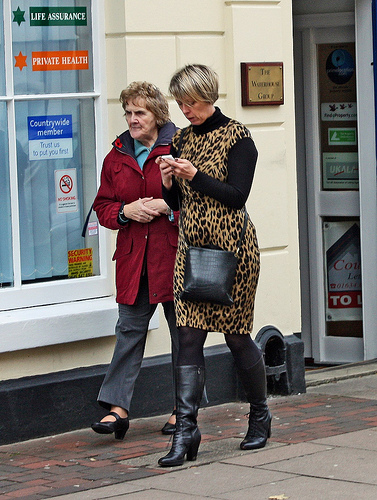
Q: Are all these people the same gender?
A: Yes, all the people are female.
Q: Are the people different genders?
A: No, all the people are female.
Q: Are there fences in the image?
A: No, there are no fences.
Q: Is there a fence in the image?
A: No, there are no fences.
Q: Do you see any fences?
A: No, there are no fences.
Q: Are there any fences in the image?
A: No, there are no fences.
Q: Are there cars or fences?
A: No, there are no fences or cars.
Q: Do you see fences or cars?
A: No, there are no fences or cars.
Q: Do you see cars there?
A: No, there are no cars.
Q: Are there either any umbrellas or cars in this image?
A: No, there are no cars or umbrellas.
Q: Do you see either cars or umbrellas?
A: No, there are no cars or umbrellas.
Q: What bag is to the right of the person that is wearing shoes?
A: The bag is a handbag.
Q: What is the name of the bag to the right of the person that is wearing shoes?
A: The bag is a handbag.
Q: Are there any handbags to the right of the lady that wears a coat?
A: Yes, there is a handbag to the right of the lady.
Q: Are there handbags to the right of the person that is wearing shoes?
A: Yes, there is a handbag to the right of the lady.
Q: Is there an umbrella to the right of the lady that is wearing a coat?
A: No, there is a handbag to the right of the lady.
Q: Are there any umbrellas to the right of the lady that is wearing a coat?
A: No, there is a handbag to the right of the lady.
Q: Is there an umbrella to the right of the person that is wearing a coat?
A: No, there is a handbag to the right of the lady.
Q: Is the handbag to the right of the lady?
A: Yes, the handbag is to the right of the lady.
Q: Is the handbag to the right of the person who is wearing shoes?
A: Yes, the handbag is to the right of the lady.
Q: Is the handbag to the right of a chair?
A: No, the handbag is to the right of the lady.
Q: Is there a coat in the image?
A: Yes, there is a coat.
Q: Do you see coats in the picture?
A: Yes, there is a coat.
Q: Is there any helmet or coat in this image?
A: Yes, there is a coat.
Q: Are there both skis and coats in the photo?
A: No, there is a coat but no skis.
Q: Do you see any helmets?
A: No, there are no helmets.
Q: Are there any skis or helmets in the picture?
A: No, there are no helmets or skis.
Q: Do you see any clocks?
A: No, there are no clocks.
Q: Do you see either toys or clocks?
A: No, there are no clocks or toys.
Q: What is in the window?
A: The sticker is in the window.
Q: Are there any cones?
A: No, there are no cones.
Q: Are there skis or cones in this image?
A: No, there are no cones or skis.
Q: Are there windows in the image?
A: Yes, there is a window.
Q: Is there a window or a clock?
A: Yes, there is a window.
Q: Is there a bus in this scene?
A: No, there are no buses.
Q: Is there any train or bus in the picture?
A: No, there are no buses or trains.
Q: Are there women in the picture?
A: Yes, there are women.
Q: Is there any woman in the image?
A: Yes, there are women.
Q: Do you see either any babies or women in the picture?
A: Yes, there are women.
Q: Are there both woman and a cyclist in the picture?
A: No, there are women but no cyclists.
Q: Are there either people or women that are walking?
A: Yes, the women are walking.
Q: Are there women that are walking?
A: Yes, there are women that are walking.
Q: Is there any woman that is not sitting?
A: Yes, there are women that are walking.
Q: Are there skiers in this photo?
A: No, there are no skiers.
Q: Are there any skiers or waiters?
A: No, there are no skiers or waiters.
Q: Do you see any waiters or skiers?
A: No, there are no skiers or waiters.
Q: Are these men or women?
A: These are women.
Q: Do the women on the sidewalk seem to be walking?
A: Yes, the women are walking.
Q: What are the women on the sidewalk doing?
A: The women are walking.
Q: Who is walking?
A: The women are walking.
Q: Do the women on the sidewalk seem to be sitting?
A: No, the women are walking.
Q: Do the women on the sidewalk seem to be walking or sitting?
A: The women are walking.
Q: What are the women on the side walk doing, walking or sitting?
A: The women are walking.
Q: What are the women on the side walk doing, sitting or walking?
A: The women are walking.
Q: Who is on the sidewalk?
A: The women are on the sidewalk.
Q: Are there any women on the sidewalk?
A: Yes, there are women on the sidewalk.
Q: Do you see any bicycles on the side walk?
A: No, there are women on the side walk.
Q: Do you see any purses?
A: Yes, there is a purse.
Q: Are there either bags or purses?
A: Yes, there is a purse.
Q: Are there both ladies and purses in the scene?
A: Yes, there are both a purse and a lady.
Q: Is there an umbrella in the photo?
A: No, there are no umbrellas.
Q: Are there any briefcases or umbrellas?
A: No, there are no umbrellas or briefcases.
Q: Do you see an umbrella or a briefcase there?
A: No, there are no umbrellas or briefcases.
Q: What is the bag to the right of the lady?
A: The bag is a purse.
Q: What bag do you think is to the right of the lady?
A: The bag is a purse.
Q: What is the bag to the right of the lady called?
A: The bag is a purse.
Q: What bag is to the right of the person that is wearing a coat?
A: The bag is a purse.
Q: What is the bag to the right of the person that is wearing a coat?
A: The bag is a purse.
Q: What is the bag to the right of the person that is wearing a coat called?
A: The bag is a purse.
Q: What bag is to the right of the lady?
A: The bag is a purse.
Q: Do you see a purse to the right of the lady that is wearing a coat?
A: Yes, there is a purse to the right of the lady.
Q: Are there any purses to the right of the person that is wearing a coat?
A: Yes, there is a purse to the right of the lady.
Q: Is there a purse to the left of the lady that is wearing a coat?
A: No, the purse is to the right of the lady.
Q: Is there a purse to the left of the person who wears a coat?
A: No, the purse is to the right of the lady.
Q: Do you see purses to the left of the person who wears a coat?
A: No, the purse is to the right of the lady.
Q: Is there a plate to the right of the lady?
A: No, there is a purse to the right of the lady.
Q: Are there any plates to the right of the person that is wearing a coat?
A: No, there is a purse to the right of the lady.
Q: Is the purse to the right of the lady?
A: Yes, the purse is to the right of the lady.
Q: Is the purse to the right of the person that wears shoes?
A: Yes, the purse is to the right of the lady.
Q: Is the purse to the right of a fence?
A: No, the purse is to the right of the lady.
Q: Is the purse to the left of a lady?
A: No, the purse is to the right of a lady.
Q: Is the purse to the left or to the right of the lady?
A: The purse is to the right of the lady.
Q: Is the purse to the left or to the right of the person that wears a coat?
A: The purse is to the right of the lady.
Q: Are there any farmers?
A: No, there are no farmers.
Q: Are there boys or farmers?
A: No, there are no farmers or boys.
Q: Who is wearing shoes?
A: The lady is wearing shoes.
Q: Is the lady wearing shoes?
A: Yes, the lady is wearing shoes.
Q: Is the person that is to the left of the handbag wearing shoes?
A: Yes, the lady is wearing shoes.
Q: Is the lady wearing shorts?
A: No, the lady is wearing shoes.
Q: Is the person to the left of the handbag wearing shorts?
A: No, the lady is wearing shoes.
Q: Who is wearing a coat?
A: The lady is wearing a coat.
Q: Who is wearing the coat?
A: The lady is wearing a coat.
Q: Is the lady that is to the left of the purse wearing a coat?
A: Yes, the lady is wearing a coat.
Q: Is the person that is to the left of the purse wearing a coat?
A: Yes, the lady is wearing a coat.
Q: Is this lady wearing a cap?
A: No, the lady is wearing a coat.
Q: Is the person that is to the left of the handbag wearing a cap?
A: No, the lady is wearing a coat.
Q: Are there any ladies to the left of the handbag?
A: Yes, there is a lady to the left of the handbag.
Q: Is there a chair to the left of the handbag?
A: No, there is a lady to the left of the handbag.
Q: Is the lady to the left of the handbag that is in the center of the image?
A: Yes, the lady is to the left of the handbag.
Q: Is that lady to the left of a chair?
A: No, the lady is to the left of the handbag.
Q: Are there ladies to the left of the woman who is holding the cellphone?
A: Yes, there is a lady to the left of the woman.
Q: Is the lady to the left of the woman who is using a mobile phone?
A: Yes, the lady is to the left of the woman.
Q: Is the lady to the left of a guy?
A: No, the lady is to the left of the woman.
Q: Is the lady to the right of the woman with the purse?
A: No, the lady is to the left of the woman.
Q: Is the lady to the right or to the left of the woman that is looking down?
A: The lady is to the left of the woman.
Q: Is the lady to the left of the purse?
A: Yes, the lady is to the left of the purse.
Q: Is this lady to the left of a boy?
A: No, the lady is to the left of the purse.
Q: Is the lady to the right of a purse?
A: No, the lady is to the left of a purse.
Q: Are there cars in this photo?
A: No, there are no cars.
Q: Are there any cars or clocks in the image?
A: No, there are no cars or clocks.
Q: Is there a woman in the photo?
A: Yes, there is a woman.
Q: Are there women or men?
A: Yes, there is a woman.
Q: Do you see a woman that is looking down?
A: Yes, there is a woman that is looking down.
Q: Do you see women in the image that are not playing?
A: Yes, there is a woman that is looking down .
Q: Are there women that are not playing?
A: Yes, there is a woman that is looking down.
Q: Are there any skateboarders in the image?
A: No, there are no skateboarders.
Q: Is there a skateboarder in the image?
A: No, there are no skateboarders.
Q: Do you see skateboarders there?
A: No, there are no skateboarders.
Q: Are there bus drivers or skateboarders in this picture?
A: No, there are no skateboarders or bus drivers.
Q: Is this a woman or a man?
A: This is a woman.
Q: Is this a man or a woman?
A: This is a woman.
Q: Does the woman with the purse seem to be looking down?
A: Yes, the woman is looking down.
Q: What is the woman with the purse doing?
A: The woman is looking down.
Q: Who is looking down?
A: The woman is looking down.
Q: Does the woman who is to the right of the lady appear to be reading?
A: No, the woman is looking down.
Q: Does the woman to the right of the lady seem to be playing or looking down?
A: The woman is looking down.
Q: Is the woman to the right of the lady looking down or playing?
A: The woman is looking down.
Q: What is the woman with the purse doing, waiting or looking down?
A: The woman is looking down.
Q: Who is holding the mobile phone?
A: The woman is holding the mobile phone.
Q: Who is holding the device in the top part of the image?
A: The woman is holding the mobile phone.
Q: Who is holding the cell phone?
A: The woman is holding the mobile phone.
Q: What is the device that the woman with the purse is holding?
A: The device is a cell phone.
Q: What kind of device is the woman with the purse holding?
A: The woman is holding the cell phone.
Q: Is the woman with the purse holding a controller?
A: No, the woman is holding a cell phone.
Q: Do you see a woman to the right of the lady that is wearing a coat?
A: Yes, there is a woman to the right of the lady.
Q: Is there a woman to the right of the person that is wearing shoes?
A: Yes, there is a woman to the right of the lady.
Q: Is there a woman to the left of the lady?
A: No, the woman is to the right of the lady.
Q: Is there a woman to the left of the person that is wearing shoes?
A: No, the woman is to the right of the lady.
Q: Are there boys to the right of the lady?
A: No, there is a woman to the right of the lady.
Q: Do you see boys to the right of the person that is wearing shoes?
A: No, there is a woman to the right of the lady.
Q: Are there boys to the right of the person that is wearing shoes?
A: No, there is a woman to the right of the lady.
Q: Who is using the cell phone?
A: The woman is using the cell phone.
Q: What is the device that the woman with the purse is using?
A: The device is a cell phone.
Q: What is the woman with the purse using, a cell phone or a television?
A: The woman is using a cell phone.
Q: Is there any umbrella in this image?
A: No, there are no umbrellas.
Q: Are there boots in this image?
A: Yes, there are boots.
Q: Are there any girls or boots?
A: Yes, there are boots.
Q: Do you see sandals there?
A: No, there are no sandals.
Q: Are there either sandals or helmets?
A: No, there are no sandals or helmets.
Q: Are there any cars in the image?
A: No, there are no cars.